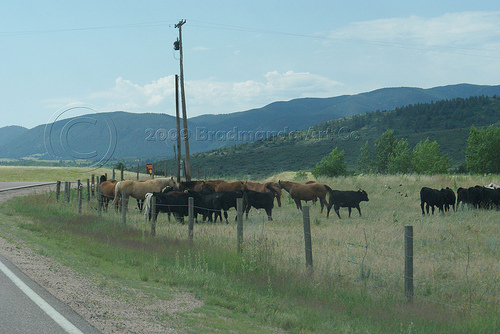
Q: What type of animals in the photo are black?
A: Cow.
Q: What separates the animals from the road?
A: Fence.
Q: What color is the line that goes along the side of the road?
A: White.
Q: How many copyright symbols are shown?
A: One.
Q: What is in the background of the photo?
A: Mountains.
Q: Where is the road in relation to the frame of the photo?
A: Left.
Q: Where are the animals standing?
A: Pasture.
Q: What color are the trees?
A: Green.